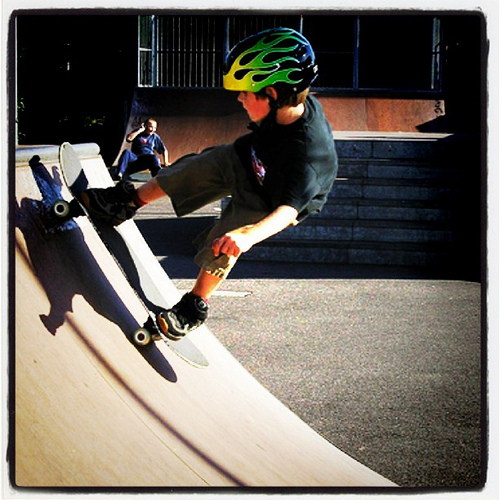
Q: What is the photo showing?
A: It is showing a pavement.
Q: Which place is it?
A: It is a pavement.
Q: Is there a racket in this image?
A: No, there are no rackets.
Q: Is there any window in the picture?
A: Yes, there is a window.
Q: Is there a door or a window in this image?
A: Yes, there is a window.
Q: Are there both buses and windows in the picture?
A: No, there is a window but no buses.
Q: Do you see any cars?
A: No, there are no cars.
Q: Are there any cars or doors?
A: No, there are no cars or doors.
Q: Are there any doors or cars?
A: No, there are no cars or doors.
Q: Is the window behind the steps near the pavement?
A: Yes, the window is behind the steps.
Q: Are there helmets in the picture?
A: Yes, there is a helmet.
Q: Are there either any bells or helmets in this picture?
A: Yes, there is a helmet.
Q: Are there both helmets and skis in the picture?
A: No, there is a helmet but no skis.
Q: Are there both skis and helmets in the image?
A: No, there is a helmet but no skis.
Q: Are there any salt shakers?
A: No, there are no salt shakers.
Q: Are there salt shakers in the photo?
A: No, there are no salt shakers.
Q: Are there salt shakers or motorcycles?
A: No, there are no salt shakers or motorcycles.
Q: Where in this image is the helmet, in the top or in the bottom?
A: The helmet is in the top of the image.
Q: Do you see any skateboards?
A: Yes, there is a skateboard.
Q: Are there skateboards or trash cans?
A: Yes, there is a skateboard.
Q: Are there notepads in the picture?
A: No, there are no notepads.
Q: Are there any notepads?
A: No, there are no notepads.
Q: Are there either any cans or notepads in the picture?
A: No, there are no notepads or cans.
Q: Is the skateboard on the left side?
A: Yes, the skateboard is on the left of the image.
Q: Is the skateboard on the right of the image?
A: No, the skateboard is on the left of the image.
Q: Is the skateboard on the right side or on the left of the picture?
A: The skateboard is on the left of the image.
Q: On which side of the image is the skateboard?
A: The skateboard is on the left of the image.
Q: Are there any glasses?
A: No, there are no glasses.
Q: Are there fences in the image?
A: Yes, there is a fence.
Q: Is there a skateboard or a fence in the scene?
A: Yes, there is a fence.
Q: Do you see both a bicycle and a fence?
A: No, there is a fence but no bicycles.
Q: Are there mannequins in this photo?
A: No, there are no mannequins.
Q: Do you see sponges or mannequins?
A: No, there are no mannequins or sponges.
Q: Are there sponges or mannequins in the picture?
A: No, there are no mannequins or sponges.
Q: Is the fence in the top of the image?
A: Yes, the fence is in the top of the image.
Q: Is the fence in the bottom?
A: No, the fence is in the top of the image.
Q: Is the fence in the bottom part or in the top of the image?
A: The fence is in the top of the image.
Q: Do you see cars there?
A: No, there are no cars.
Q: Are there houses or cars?
A: No, there are no cars or houses.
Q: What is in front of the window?
A: The steps are in front of the window.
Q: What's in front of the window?
A: The steps are in front of the window.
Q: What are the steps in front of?
A: The steps are in front of the window.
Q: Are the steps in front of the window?
A: Yes, the steps are in front of the window.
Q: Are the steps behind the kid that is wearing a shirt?
A: Yes, the steps are behind the kid.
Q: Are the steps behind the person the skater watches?
A: Yes, the steps are behind the kid.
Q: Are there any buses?
A: No, there are no buses.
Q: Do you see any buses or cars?
A: No, there are no buses or cars.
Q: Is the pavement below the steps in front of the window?
A: Yes, the pavement is below the steps.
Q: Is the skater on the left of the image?
A: Yes, the skater is on the left of the image.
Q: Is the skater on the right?
A: No, the skater is on the left of the image.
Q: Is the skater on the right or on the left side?
A: The skater is on the left of the image.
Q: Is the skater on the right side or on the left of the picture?
A: The skater is on the left of the image.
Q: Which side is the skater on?
A: The skater is on the left of the image.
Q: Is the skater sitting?
A: Yes, the skater is sitting.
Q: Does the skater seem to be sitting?
A: Yes, the skater is sitting.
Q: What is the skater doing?
A: The skater is sitting.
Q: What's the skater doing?
A: The skater is sitting.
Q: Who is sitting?
A: The skater is sitting.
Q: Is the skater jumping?
A: No, the skater is sitting.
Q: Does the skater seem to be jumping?
A: No, the skater is sitting.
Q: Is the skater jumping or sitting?
A: The skater is sitting.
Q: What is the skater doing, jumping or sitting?
A: The skater is sitting.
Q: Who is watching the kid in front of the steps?
A: The skater is watching the kid.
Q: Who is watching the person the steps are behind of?
A: The skater is watching the kid.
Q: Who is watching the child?
A: The skater is watching the kid.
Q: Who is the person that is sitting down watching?
A: The skater is watching the kid.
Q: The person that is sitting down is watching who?
A: The skater is watching the kid.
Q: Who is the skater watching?
A: The skater is watching the kid.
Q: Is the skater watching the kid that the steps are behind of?
A: Yes, the skater is watching the kid.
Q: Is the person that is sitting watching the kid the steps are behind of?
A: Yes, the skater is watching the kid.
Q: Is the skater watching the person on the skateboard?
A: Yes, the skater is watching the kid.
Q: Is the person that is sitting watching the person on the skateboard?
A: Yes, the skater is watching the kid.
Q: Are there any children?
A: Yes, there is a child.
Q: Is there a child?
A: Yes, there is a child.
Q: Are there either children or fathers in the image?
A: Yes, there is a child.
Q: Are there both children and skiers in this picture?
A: No, there is a child but no skiers.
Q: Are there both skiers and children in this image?
A: No, there is a child but no skiers.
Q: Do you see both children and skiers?
A: No, there is a child but no skiers.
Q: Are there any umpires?
A: No, there are no umpires.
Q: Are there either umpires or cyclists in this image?
A: No, there are no umpires or cyclists.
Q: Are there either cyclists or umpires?
A: No, there are no umpires or cyclists.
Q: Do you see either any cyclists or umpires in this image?
A: No, there are no umpires or cyclists.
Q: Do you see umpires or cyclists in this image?
A: No, there are no umpires or cyclists.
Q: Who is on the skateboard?
A: The child is on the skateboard.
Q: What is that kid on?
A: The kid is on the skateboard.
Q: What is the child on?
A: The kid is on the skateboard.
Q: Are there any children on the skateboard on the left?
A: Yes, there is a child on the skateboard.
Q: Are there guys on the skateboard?
A: No, there is a child on the skateboard.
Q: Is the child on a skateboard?
A: Yes, the child is on a skateboard.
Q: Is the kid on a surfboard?
A: No, the kid is on a skateboard.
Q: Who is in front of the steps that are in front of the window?
A: The child is in front of the steps.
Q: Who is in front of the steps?
A: The child is in front of the steps.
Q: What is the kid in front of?
A: The kid is in front of the steps.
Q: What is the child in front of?
A: The kid is in front of the steps.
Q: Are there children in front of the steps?
A: Yes, there is a child in front of the steps.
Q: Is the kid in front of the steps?
A: Yes, the kid is in front of the steps.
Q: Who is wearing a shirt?
A: The kid is wearing a shirt.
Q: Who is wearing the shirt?
A: The kid is wearing a shirt.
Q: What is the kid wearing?
A: The kid is wearing a shirt.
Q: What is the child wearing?
A: The kid is wearing a shirt.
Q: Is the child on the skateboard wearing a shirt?
A: Yes, the kid is wearing a shirt.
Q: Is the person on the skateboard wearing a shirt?
A: Yes, the kid is wearing a shirt.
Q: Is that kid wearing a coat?
A: No, the kid is wearing a shirt.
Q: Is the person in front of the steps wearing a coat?
A: No, the kid is wearing a shirt.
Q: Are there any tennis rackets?
A: No, there are no tennis rackets.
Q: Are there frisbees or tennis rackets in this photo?
A: No, there are no tennis rackets or frisbees.